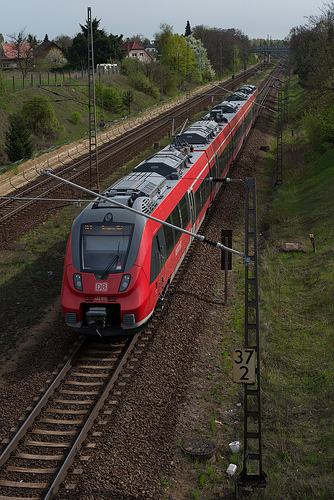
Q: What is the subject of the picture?
A: Train.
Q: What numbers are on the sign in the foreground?
A: 37 2.